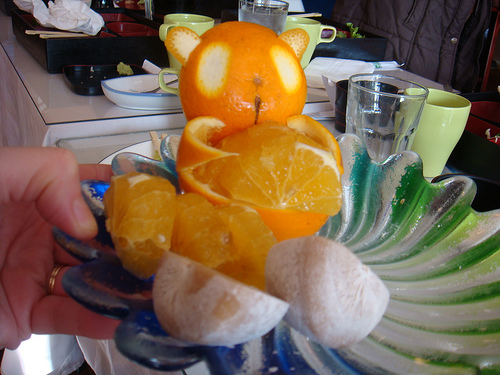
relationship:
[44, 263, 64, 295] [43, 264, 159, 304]
band on finger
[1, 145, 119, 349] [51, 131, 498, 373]
hand holding bowl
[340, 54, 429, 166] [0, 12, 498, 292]
glass on counter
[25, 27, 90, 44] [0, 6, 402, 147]
utensil on counter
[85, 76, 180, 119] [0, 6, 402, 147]
dish on counter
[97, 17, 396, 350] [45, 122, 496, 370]
oranges inside dish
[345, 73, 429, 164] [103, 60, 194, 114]
glass holding dish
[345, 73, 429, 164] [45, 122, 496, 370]
glass behind dish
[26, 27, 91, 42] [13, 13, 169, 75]
chopsticks in tray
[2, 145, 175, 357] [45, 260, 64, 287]
person wearing rings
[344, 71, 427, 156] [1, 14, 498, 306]
cup on table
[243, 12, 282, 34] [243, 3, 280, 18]
water in glass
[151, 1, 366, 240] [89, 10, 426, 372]
bear made of oranges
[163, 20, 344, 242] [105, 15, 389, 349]
bear made of fruit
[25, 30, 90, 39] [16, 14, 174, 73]
chopsticks in box